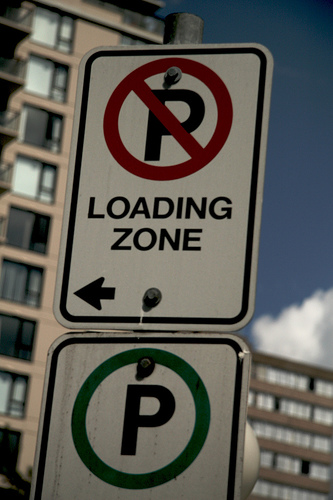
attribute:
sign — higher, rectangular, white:
[53, 43, 273, 333]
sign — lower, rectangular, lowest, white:
[29, 330, 251, 499]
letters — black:
[88, 88, 205, 455]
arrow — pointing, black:
[72, 277, 116, 311]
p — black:
[120, 384, 175, 456]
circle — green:
[71, 348, 211, 490]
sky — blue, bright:
[155, 1, 331, 352]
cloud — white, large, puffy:
[250, 286, 332, 369]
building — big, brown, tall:
[0, 0, 332, 499]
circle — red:
[104, 58, 233, 182]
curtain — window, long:
[31, 8, 58, 48]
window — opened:
[308, 376, 315, 392]